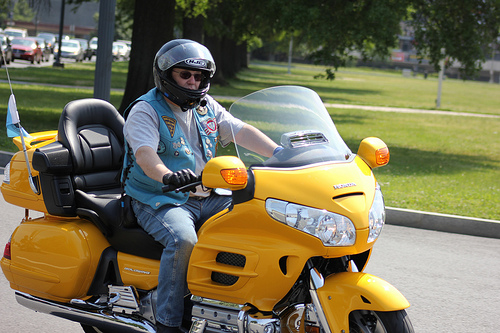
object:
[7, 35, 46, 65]
car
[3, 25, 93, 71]
street